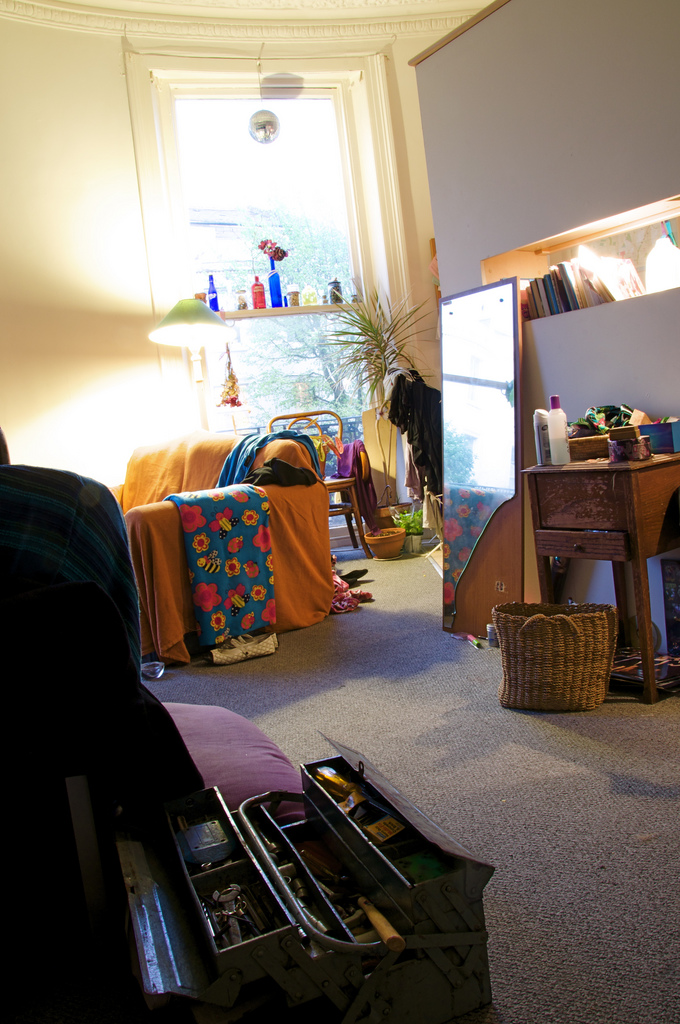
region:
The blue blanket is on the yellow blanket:
[106, 448, 377, 691]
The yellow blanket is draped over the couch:
[75, 420, 385, 688]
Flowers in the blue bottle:
[242, 221, 323, 331]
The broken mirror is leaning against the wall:
[401, 258, 537, 703]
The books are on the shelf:
[463, 194, 678, 340]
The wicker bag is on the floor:
[491, 588, 638, 756]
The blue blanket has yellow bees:
[149, 463, 313, 692]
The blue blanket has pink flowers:
[143, 460, 303, 649]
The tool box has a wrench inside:
[201, 866, 280, 968]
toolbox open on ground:
[52, 765, 503, 1021]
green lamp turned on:
[147, 292, 234, 362]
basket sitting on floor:
[490, 600, 619, 713]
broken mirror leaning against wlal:
[436, 275, 521, 640]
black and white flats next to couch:
[203, 635, 298, 669]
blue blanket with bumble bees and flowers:
[166, 484, 277, 650]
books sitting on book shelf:
[517, 248, 641, 318]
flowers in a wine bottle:
[264, 237, 286, 308]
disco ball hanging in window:
[247, 109, 282, 145]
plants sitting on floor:
[362, 510, 424, 560]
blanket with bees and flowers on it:
[168, 478, 285, 648]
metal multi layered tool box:
[74, 742, 500, 1012]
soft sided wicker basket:
[491, 596, 627, 717]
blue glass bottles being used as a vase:
[259, 230, 290, 310]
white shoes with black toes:
[201, 626, 287, 664]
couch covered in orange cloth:
[102, 439, 346, 668]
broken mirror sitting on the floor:
[437, 278, 526, 649]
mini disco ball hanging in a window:
[243, 107, 281, 145]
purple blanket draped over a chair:
[333, 434, 379, 535]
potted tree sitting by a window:
[314, 281, 432, 527]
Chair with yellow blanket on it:
[85, 421, 395, 674]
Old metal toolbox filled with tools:
[98, 780, 551, 1018]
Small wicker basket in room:
[473, 586, 626, 731]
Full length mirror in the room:
[417, 268, 548, 651]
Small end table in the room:
[518, 427, 673, 705]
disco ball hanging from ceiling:
[231, 103, 294, 142]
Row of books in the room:
[493, 257, 646, 317]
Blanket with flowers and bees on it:
[159, 482, 293, 657]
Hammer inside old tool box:
[327, 877, 415, 952]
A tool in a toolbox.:
[216, 881, 239, 952]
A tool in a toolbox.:
[341, 886, 405, 949]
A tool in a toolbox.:
[275, 860, 293, 873]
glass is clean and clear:
[224, 336, 390, 440]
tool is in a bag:
[183, 813, 228, 864]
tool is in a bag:
[211, 883, 243, 949]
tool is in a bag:
[349, 891, 406, 947]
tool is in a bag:
[366, 813, 402, 842]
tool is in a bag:
[334, 789, 363, 816]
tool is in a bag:
[314, 768, 354, 795]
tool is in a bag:
[270, 862, 296, 880]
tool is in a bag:
[296, 895, 330, 934]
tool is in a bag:
[298, 845, 341, 884]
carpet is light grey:
[436, 741, 532, 843]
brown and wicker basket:
[493, 589, 625, 718]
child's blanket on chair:
[173, 485, 298, 703]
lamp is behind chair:
[138, 272, 242, 344]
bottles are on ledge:
[173, 236, 380, 313]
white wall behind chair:
[443, 172, 500, 240]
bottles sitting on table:
[525, 364, 570, 492]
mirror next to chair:
[414, 271, 519, 641]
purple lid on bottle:
[543, 382, 568, 405]